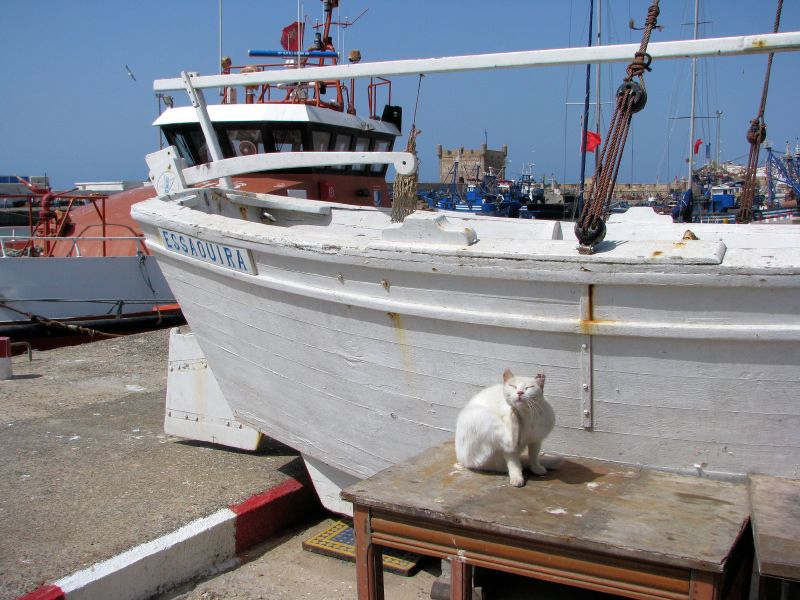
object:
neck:
[500, 367, 549, 413]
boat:
[126, 0, 798, 586]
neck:
[338, 438, 763, 600]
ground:
[592, 219, 632, 259]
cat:
[452, 369, 559, 490]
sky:
[0, 0, 165, 190]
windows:
[140, 143, 417, 197]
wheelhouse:
[143, 0, 409, 207]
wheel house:
[143, 105, 405, 178]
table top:
[342, 433, 761, 579]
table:
[340, 438, 757, 600]